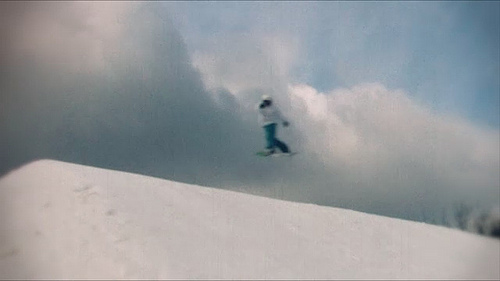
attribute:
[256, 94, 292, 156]
person — flying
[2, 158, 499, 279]
slope — large, snowy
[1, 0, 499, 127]
sky — full, blue, cloudy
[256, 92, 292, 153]
man — snowboarding, airborne, jumping, dressed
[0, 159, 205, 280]
hill — section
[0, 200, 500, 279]
ground — snowy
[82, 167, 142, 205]
snow — mound, pure, white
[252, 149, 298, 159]
snowboard — thin, airborne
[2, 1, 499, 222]
clouds — white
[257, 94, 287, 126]
hoodie — white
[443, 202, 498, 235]
trees — back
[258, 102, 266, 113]
arm — pointing